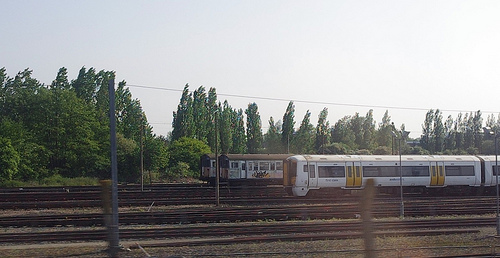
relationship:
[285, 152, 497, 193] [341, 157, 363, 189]
train with yellow doors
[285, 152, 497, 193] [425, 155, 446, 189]
train with door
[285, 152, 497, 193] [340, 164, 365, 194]
train with doors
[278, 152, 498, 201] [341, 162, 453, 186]
train with doors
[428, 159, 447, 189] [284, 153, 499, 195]
yellow doors of train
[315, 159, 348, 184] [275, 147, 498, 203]
window of train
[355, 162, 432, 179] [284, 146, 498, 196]
window of train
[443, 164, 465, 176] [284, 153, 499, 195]
passenger window of train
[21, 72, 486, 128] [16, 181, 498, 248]
power lines above tracks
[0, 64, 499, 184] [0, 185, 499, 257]
trees behind tracks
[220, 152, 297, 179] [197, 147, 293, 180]
wall on side of a building